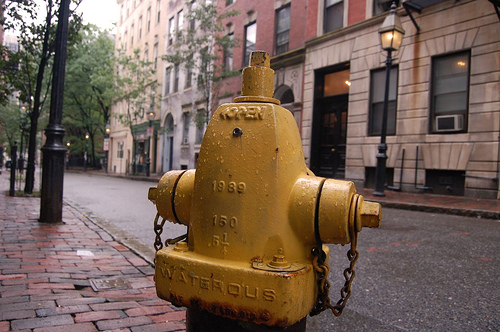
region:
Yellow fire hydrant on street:
[141, 46, 391, 328]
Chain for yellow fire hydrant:
[297, 235, 367, 320]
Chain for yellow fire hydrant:
[145, 211, 170, 247]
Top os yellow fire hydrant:
[231, 43, 288, 103]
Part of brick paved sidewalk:
[38, 259, 115, 310]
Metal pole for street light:
[30, 2, 76, 225]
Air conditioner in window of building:
[425, 110, 465, 130]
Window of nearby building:
[425, 52, 472, 137]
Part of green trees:
[70, 64, 109, 111]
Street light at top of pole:
[373, 5, 407, 54]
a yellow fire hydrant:
[144, 43, 385, 329]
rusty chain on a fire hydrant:
[313, 236, 363, 316]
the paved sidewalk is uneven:
[0, 182, 195, 330]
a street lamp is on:
[367, 4, 407, 197]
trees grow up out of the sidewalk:
[5, 3, 55, 200]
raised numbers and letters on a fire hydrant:
[160, 105, 284, 307]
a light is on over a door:
[304, 58, 354, 182]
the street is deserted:
[4, 128, 499, 329]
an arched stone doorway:
[159, 107, 179, 182]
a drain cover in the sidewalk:
[86, 273, 136, 292]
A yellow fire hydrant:
[115, 50, 385, 323]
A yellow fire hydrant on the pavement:
[128, 40, 383, 328]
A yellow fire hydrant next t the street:
[129, 30, 409, 329]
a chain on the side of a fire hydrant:
[301, 173, 395, 322]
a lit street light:
[355, 3, 415, 215]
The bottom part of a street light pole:
[35, 2, 85, 259]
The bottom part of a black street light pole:
[360, 72, 411, 195]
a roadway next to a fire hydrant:
[66, 125, 398, 328]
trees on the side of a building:
[32, 12, 135, 173]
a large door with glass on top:
[296, 60, 361, 197]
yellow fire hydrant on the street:
[140, 41, 386, 328]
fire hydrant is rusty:
[136, 44, 388, 330]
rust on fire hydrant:
[150, 287, 292, 330]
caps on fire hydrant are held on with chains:
[134, 46, 391, 328]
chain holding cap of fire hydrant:
[300, 219, 367, 322]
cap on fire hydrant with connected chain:
[299, 164, 382, 316]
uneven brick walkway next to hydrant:
[2, 187, 191, 329]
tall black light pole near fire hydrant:
[30, 3, 79, 230]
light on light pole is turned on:
[370, 14, 410, 59]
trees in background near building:
[12, 27, 149, 176]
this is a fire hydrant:
[140, 28, 438, 330]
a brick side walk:
[5, 205, 182, 330]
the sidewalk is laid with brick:
[4, 228, 169, 330]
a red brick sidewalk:
[4, 219, 199, 329]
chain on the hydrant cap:
[303, 228, 367, 319]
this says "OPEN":
[201, 96, 286, 119]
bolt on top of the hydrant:
[235, 37, 290, 69]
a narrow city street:
[62, 160, 498, 330]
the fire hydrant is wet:
[142, 41, 384, 329]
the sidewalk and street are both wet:
[64, 156, 191, 330]